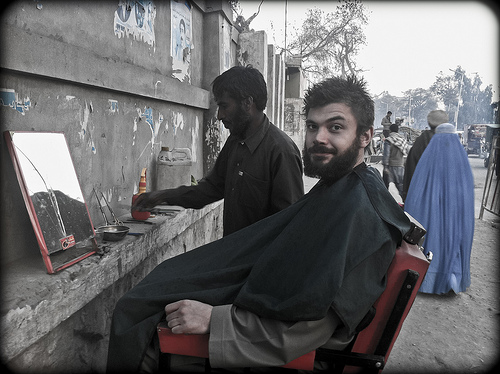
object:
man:
[105, 73, 411, 373]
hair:
[298, 73, 376, 153]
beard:
[301, 135, 359, 181]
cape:
[107, 162, 412, 374]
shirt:
[208, 303, 358, 368]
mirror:
[7, 131, 100, 275]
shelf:
[0, 197, 224, 367]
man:
[131, 63, 306, 239]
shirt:
[170, 112, 306, 239]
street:
[302, 153, 499, 373]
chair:
[158, 211, 435, 374]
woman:
[404, 123, 475, 296]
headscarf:
[404, 123, 475, 297]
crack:
[13, 144, 66, 237]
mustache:
[308, 145, 337, 154]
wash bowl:
[98, 225, 130, 241]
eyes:
[306, 123, 342, 131]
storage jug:
[156, 146, 194, 191]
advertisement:
[171, 0, 194, 86]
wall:
[0, 0, 206, 373]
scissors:
[100, 191, 125, 226]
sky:
[232, 2, 499, 111]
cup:
[132, 194, 151, 220]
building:
[0, 0, 306, 373]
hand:
[164, 299, 213, 336]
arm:
[225, 213, 370, 341]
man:
[403, 110, 449, 202]